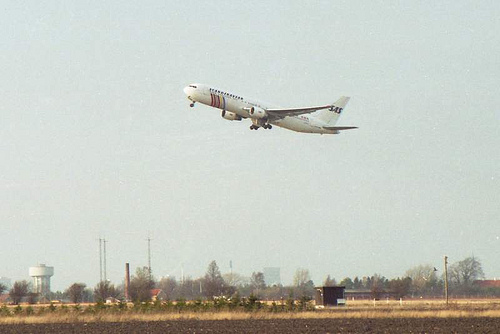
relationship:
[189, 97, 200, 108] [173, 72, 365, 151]
gear on plane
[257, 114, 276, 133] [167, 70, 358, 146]
wheel of plane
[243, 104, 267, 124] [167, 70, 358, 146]
engine of plane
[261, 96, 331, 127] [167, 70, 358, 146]
wing of plane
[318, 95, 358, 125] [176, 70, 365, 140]
fin of plane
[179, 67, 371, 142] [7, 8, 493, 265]
airplane flying in sky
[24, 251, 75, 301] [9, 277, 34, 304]
tower by tree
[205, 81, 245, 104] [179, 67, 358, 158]
windows on airplane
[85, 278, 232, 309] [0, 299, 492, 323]
bushes by field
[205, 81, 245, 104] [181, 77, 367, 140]
windows on side of plane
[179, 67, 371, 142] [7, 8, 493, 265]
airplane in sky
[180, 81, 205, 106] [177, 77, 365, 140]
nose of airplane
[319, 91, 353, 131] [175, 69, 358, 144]
tail of airplane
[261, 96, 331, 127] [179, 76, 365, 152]
wing of airplane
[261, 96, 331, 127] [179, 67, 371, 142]
wing of airplane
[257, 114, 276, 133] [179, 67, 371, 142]
wheel of airplane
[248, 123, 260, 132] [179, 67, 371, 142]
wheel of airplane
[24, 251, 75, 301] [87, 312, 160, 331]
tower on ground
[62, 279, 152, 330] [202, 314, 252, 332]
trees in field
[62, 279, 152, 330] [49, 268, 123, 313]
trees in field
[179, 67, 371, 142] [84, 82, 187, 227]
airplane in air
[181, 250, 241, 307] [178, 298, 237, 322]
tree on ground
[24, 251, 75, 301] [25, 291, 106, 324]
tower on ground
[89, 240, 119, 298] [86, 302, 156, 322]
poles on ground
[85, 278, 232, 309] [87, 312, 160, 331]
bushes on ground